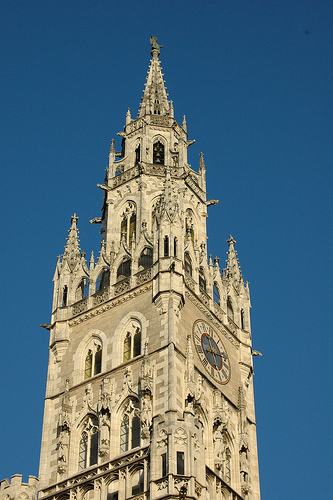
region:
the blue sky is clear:
[221, 67, 299, 190]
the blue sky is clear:
[264, 189, 301, 371]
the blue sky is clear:
[274, 234, 301, 434]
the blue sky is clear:
[16, 190, 55, 393]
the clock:
[169, 306, 247, 403]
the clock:
[183, 301, 226, 388]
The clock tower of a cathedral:
[15, 35, 272, 498]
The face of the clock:
[189, 314, 231, 383]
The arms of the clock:
[205, 335, 223, 368]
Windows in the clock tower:
[73, 419, 103, 473]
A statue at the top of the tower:
[144, 31, 162, 49]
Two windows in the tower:
[120, 328, 145, 358]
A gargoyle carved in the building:
[36, 320, 50, 335]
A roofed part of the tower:
[155, 164, 184, 308]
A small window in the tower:
[168, 443, 188, 478]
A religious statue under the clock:
[209, 422, 229, 475]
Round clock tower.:
[189, 312, 233, 384]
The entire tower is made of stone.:
[31, 28, 261, 490]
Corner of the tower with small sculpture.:
[168, 420, 187, 448]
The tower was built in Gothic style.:
[31, 30, 259, 485]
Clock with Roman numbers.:
[189, 313, 234, 390]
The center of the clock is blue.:
[185, 312, 230, 383]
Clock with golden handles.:
[186, 316, 233, 389]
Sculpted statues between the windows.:
[33, 375, 266, 480]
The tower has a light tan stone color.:
[33, 59, 262, 492]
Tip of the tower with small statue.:
[147, 28, 163, 59]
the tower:
[32, 22, 275, 497]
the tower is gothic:
[28, 24, 278, 479]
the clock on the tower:
[172, 310, 240, 377]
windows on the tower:
[72, 383, 142, 444]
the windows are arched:
[54, 384, 154, 463]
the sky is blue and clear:
[187, 13, 326, 227]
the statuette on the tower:
[131, 24, 162, 48]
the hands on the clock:
[199, 337, 224, 363]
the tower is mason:
[31, 23, 285, 498]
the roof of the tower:
[114, 22, 192, 119]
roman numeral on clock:
[207, 326, 216, 340]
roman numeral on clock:
[214, 337, 220, 343]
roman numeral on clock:
[222, 360, 229, 369]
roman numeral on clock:
[220, 366, 229, 379]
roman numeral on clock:
[210, 364, 215, 380]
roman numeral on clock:
[200, 355, 209, 368]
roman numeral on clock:
[195, 342, 204, 356]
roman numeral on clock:
[193, 332, 201, 342]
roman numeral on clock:
[196, 322, 202, 334]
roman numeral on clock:
[200, 322, 208, 335]